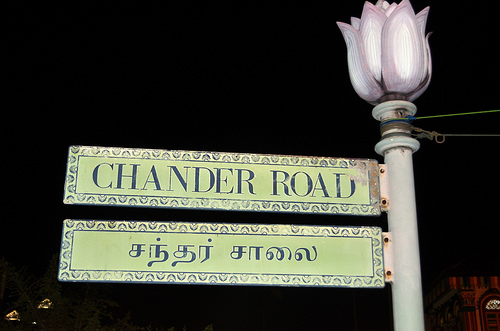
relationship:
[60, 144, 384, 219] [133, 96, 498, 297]
sign on pole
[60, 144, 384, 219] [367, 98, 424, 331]
sign on metal pole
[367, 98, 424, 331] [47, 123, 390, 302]
metal pole holding up a sign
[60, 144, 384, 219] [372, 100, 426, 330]
sign on pole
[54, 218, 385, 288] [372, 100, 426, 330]
sign on pole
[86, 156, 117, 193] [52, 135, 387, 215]
c on sign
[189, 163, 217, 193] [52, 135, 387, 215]
d on sign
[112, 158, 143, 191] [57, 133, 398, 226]
h on sign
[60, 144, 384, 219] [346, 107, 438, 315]
sign on metal pole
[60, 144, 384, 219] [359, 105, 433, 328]
sign on metal pole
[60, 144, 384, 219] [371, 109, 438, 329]
sign on pole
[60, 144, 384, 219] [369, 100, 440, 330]
sign on metal pole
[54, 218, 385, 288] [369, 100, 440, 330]
sign on metal pole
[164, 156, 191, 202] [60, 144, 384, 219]
n on sign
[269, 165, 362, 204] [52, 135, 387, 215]
road written on sign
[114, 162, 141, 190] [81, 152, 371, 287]
h written on sign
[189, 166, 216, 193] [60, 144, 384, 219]
d written on sign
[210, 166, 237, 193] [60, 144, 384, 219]
e on sign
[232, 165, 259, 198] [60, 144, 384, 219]
letter on sign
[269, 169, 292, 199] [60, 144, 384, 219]
letter on sign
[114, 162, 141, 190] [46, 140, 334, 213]
h on sign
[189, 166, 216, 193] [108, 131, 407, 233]
d on sign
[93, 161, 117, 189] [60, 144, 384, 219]
c on sign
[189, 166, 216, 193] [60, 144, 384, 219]
d on sign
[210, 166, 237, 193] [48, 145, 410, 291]
e on sign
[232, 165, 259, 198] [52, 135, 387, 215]
letter on sign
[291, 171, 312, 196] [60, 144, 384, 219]
o on sign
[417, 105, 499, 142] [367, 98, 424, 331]
wires connected to metal pole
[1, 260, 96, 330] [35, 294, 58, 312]
house with light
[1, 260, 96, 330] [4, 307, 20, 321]
house with light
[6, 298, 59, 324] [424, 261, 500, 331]
tree in front of building